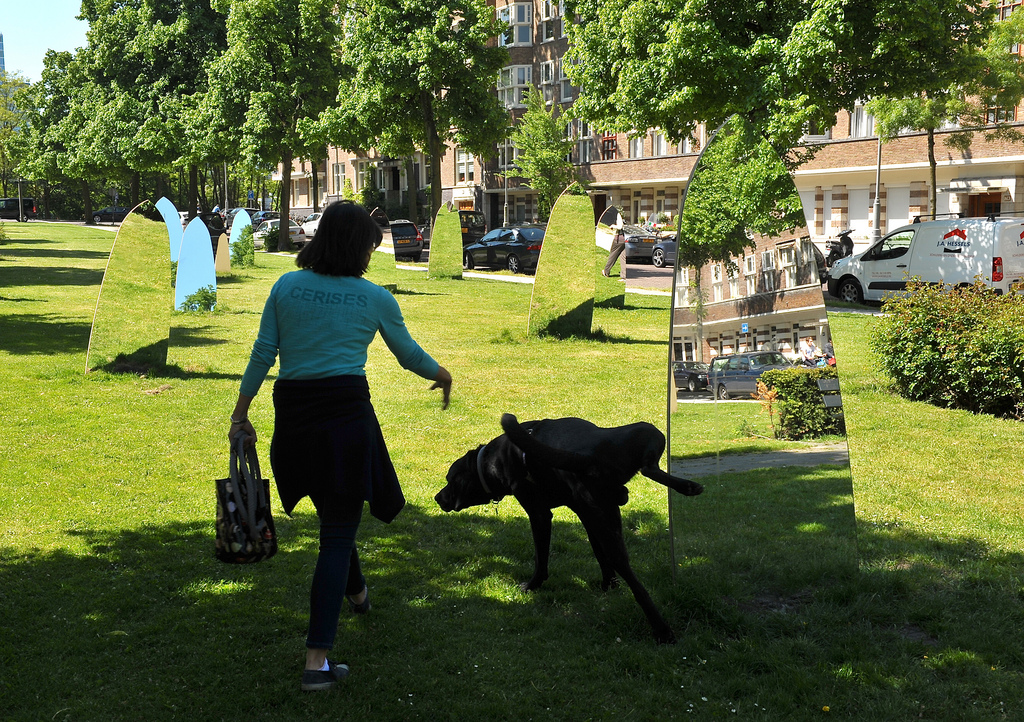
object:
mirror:
[666, 116, 861, 643]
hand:
[225, 415, 260, 447]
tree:
[747, 0, 1023, 222]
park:
[5, 214, 1014, 721]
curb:
[386, 4, 1020, 315]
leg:
[607, 420, 707, 498]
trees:
[0, 0, 312, 243]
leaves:
[200, 0, 333, 248]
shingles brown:
[591, 129, 1023, 186]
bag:
[206, 415, 284, 565]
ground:
[0, 217, 1024, 712]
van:
[821, 215, 1024, 311]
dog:
[436, 379, 713, 614]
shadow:
[0, 486, 1023, 721]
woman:
[204, 192, 456, 688]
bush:
[857, 274, 1020, 420]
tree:
[314, 1, 539, 267]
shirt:
[235, 264, 449, 394]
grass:
[5, 215, 1023, 717]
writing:
[290, 272, 372, 310]